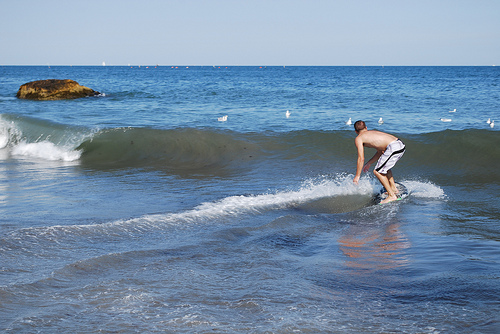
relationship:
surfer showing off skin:
[342, 117, 409, 200] [358, 133, 391, 145]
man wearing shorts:
[342, 117, 409, 200] [376, 137, 405, 177]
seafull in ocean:
[221, 109, 233, 127] [183, 70, 229, 90]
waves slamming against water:
[134, 114, 194, 153] [254, 227, 279, 260]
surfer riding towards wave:
[342, 117, 409, 200] [107, 122, 131, 145]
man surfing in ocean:
[342, 117, 409, 200] [183, 70, 229, 90]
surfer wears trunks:
[342, 117, 409, 200] [374, 142, 401, 170]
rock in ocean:
[4, 67, 92, 102] [183, 70, 229, 90]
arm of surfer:
[355, 139, 364, 186] [342, 117, 409, 200]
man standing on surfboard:
[342, 117, 409, 200] [364, 205, 399, 228]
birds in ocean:
[272, 106, 294, 120] [183, 70, 229, 90]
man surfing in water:
[342, 117, 409, 200] [254, 227, 279, 260]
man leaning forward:
[342, 117, 409, 200] [342, 118, 390, 155]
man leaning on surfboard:
[342, 117, 409, 200] [364, 205, 399, 228]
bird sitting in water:
[209, 110, 230, 123] [254, 227, 279, 260]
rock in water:
[4, 67, 92, 102] [254, 227, 279, 260]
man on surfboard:
[342, 117, 409, 200] [364, 205, 399, 228]